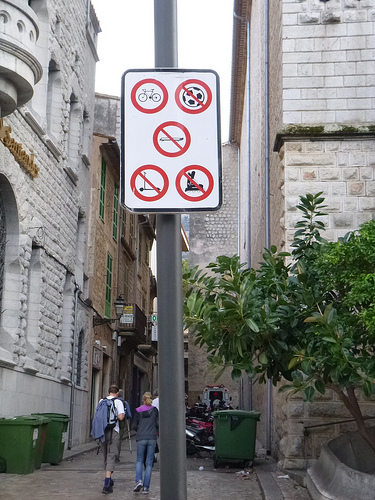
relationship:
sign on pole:
[118, 68, 220, 212] [155, 212, 187, 499]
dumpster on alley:
[208, 406, 259, 469] [10, 426, 264, 498]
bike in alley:
[184, 408, 215, 465] [10, 426, 264, 498]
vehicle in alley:
[197, 380, 236, 410] [10, 426, 264, 498]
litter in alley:
[234, 468, 253, 478] [10, 426, 264, 498]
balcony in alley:
[117, 300, 148, 341] [10, 426, 264, 498]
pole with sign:
[155, 212, 187, 499] [118, 68, 220, 212]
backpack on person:
[99, 395, 122, 425] [92, 384, 130, 493]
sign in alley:
[118, 68, 220, 212] [10, 426, 264, 498]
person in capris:
[92, 384, 130, 493] [96, 430, 125, 476]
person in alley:
[92, 384, 130, 493] [10, 426, 264, 498]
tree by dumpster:
[175, 191, 375, 447] [208, 406, 259, 469]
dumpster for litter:
[208, 406, 259, 469] [234, 468, 253, 478]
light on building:
[100, 295, 127, 332] [74, 132, 141, 439]